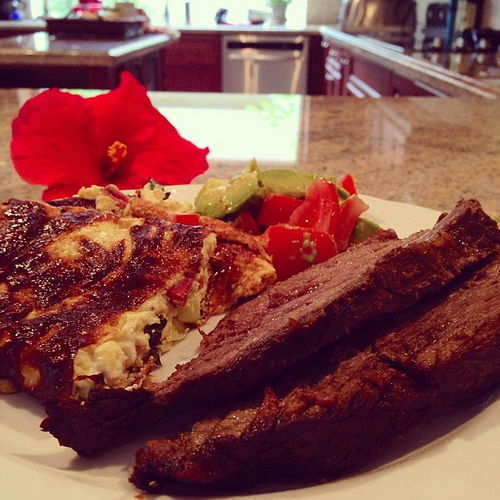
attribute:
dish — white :
[6, 187, 456, 361]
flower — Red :
[10, 67, 206, 189]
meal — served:
[8, 175, 494, 497]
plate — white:
[2, 184, 494, 495]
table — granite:
[27, 130, 490, 497]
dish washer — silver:
[219, 31, 311, 93]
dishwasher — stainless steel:
[219, 32, 308, 94]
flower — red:
[12, 85, 244, 201]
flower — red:
[6, 79, 216, 187]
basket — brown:
[42, 12, 146, 40]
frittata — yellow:
[5, 182, 278, 409]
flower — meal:
[15, 74, 215, 198]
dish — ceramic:
[21, 171, 484, 498]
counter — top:
[165, 90, 376, 195]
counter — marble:
[24, 70, 496, 369]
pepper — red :
[261, 180, 364, 276]